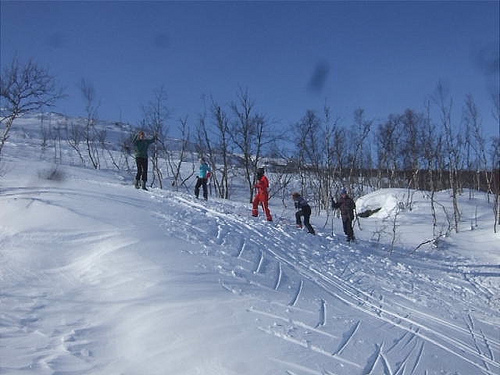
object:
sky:
[3, 2, 493, 176]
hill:
[3, 133, 495, 373]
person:
[291, 190, 314, 235]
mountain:
[0, 107, 498, 374]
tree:
[325, 115, 350, 197]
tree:
[285, 126, 317, 188]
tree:
[362, 125, 421, 191]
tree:
[236, 89, 255, 189]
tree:
[432, 99, 469, 189]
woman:
[116, 121, 163, 198]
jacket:
[137, 133, 155, 153]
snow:
[3, 245, 491, 374]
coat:
[193, 152, 225, 197]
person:
[130, 125, 160, 190]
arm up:
[129, 130, 139, 147]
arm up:
[149, 127, 159, 144]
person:
[243, 165, 277, 224]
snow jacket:
[328, 190, 359, 227]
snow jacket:
[288, 199, 314, 211]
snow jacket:
[249, 175, 276, 200]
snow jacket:
[189, 163, 221, 183]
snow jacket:
[122, 132, 164, 160]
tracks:
[167, 184, 499, 369]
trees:
[216, 99, 238, 197]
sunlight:
[41, 236, 173, 361]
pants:
[187, 178, 212, 205]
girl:
[188, 157, 212, 199]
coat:
[195, 165, 210, 178]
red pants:
[250, 194, 275, 222]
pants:
[295, 210, 315, 231]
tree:
[431, 89, 464, 241]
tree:
[461, 97, 498, 202]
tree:
[395, 114, 428, 193]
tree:
[350, 122, 377, 204]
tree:
[315, 117, 352, 204]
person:
[190, 148, 212, 195]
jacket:
[192, 159, 211, 179]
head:
[140, 133, 143, 142]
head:
[342, 190, 348, 200]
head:
[197, 157, 204, 162]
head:
[255, 167, 261, 177]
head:
[291, 192, 301, 200]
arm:
[153, 132, 165, 148]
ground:
[0, 111, 484, 363]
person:
[192, 156, 213, 198]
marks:
[224, 240, 306, 310]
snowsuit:
[332, 195, 362, 235]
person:
[328, 191, 358, 240]